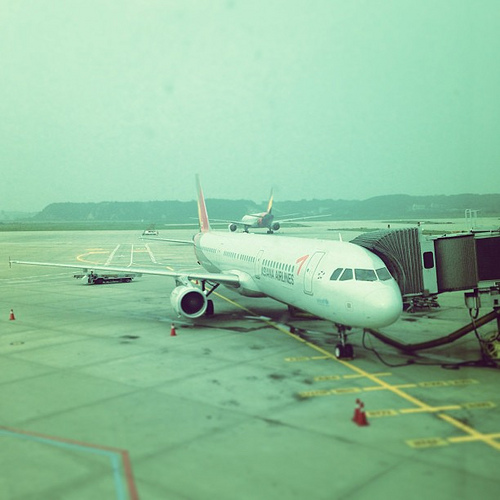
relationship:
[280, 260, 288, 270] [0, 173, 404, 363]
window on plane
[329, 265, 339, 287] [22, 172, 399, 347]
window on a vehicle